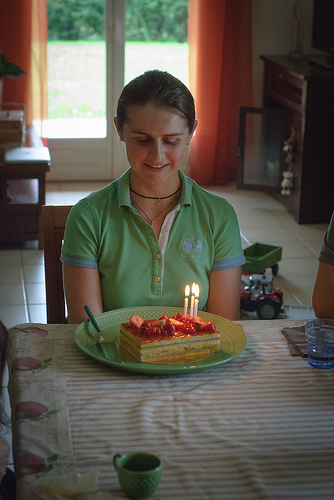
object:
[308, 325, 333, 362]
glass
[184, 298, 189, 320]
candle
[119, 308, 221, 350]
slice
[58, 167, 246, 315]
shirt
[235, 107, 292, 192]
door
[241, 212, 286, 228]
piece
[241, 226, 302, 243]
tile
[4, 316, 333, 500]
tablecloth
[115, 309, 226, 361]
cake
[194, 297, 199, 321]
candle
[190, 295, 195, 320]
candle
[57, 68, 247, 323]
woman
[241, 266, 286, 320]
truck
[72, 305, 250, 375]
plate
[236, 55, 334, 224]
cabinet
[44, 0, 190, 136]
backyard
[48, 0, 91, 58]
glass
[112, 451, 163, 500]
coffee cup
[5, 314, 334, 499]
table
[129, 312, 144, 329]
strawberries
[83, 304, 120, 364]
cake cutter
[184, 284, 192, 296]
flame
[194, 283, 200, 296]
flame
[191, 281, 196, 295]
flame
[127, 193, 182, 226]
necklaces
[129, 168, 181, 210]
neck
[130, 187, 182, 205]
nacklace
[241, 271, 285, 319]
toys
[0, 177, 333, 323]
floor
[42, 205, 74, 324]
chair